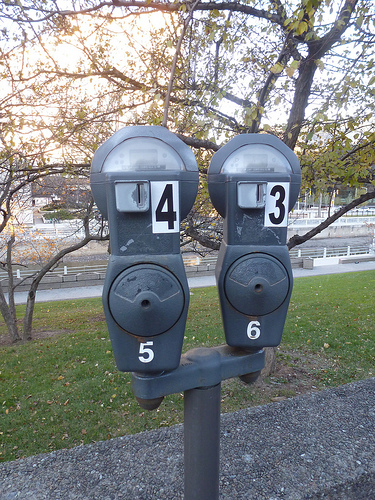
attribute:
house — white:
[33, 196, 55, 207]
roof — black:
[31, 175, 86, 195]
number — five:
[139, 340, 156, 364]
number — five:
[246, 318, 263, 339]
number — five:
[270, 181, 283, 221]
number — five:
[155, 183, 178, 230]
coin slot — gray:
[108, 178, 153, 212]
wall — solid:
[2, 376, 373, 498]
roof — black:
[29, 174, 90, 197]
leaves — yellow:
[0, 218, 62, 268]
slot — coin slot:
[134, 181, 145, 206]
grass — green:
[1, 270, 373, 447]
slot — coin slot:
[111, 174, 152, 214]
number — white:
[244, 317, 265, 342]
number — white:
[136, 337, 158, 365]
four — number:
[156, 183, 176, 229]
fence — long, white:
[12, 241, 373, 282]